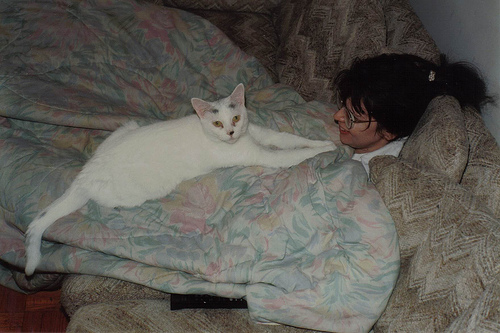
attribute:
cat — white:
[21, 276, 338, 305]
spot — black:
[205, 104, 220, 114]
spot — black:
[222, 100, 240, 109]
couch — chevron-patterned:
[58, 0, 494, 332]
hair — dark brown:
[328, 51, 498, 141]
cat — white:
[21, 77, 341, 278]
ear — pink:
[226, 79, 247, 109]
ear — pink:
[183, 95, 211, 119]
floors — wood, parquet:
[7, 290, 64, 330]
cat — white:
[18, 101, 372, 264]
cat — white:
[28, 87, 328, 259]